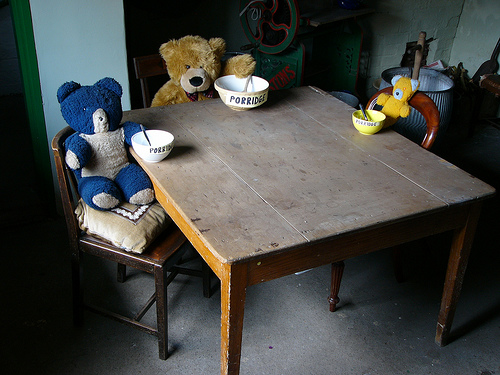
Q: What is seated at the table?
A: Stuffed bears.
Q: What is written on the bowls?
A: Porridge.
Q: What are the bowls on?
A: Table.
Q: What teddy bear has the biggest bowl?
A: The brown teddy bear.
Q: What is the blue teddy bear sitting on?
A: A brown wooden chair.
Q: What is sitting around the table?
A: Three teddy bears.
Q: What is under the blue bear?
A: A pillow.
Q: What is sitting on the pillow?
A: Blue and white toy bear.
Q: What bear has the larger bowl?
A: Light brown colored bear.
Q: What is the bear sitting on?
A: A seat cushion.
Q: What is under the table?
A: Grey color flooring.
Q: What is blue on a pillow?
A: Stuffed teddy bear.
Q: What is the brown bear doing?
A: Holding a spoon.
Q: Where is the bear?
A: On the chair.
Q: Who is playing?
A: Kids.